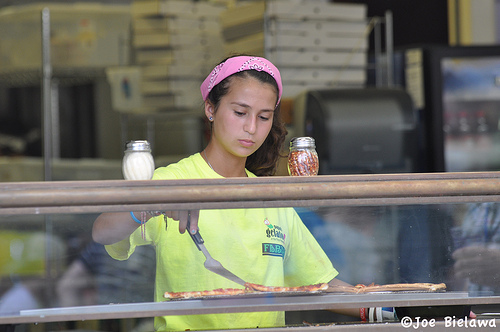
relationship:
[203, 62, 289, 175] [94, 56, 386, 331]
hair on girl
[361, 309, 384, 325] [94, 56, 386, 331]
wristband on girl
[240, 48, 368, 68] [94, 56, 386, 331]
box behind girl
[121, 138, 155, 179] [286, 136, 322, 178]
jar and shaker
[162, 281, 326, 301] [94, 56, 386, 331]
pizza by girl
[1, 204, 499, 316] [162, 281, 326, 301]
glass by pizza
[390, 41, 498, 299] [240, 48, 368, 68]
fridge by box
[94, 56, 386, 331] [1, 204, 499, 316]
girl by glass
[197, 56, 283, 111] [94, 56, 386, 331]
headband on girl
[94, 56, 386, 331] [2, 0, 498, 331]
girl in restaurant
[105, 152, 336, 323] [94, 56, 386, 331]
shirt on girl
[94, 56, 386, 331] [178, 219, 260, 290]
girl holding spatula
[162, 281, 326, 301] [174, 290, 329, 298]
pizza on a tray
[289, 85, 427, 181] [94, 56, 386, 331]
dispencer behind girl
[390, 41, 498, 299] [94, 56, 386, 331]
fridge by girl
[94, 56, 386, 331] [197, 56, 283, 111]
girl with headband